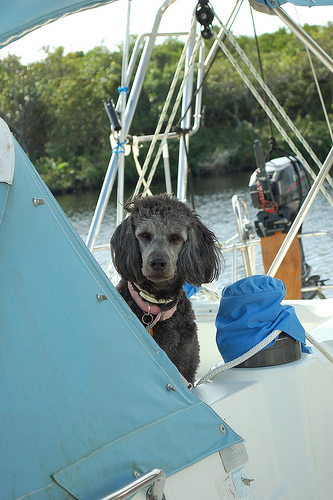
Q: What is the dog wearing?
A: A collar.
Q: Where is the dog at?
A: Boat.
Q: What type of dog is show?
A: Poodle.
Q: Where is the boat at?
A: The water.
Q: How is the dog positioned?
A: Sitting.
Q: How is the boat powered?
A: Motor.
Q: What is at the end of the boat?
A: The motor.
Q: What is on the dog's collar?
A: Tags.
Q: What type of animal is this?
A: Dog.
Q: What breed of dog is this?
A: Poodle.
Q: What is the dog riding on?
A: A boat.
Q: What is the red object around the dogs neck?
A: A collar.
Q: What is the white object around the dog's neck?
A: Flea collar.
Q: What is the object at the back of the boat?
A: The motor.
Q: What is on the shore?
A: Trees.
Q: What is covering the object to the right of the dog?
A: A blue cloth.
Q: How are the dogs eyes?
A: Open.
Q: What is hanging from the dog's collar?
A: A tag.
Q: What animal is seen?
A: Dog.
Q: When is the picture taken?
A: Daytime.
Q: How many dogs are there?
A: One.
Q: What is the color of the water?
A: Blue.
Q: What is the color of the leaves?
A: Green.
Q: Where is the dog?
A: In the boat.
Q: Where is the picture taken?
A: On the water.